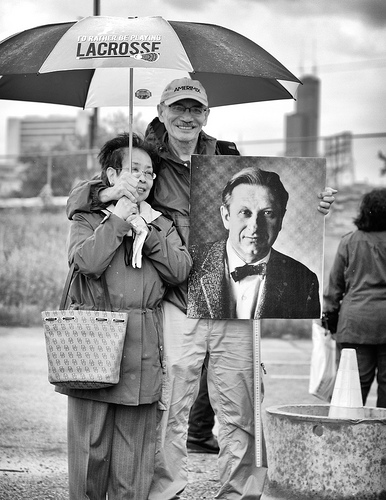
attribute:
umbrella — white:
[88, 20, 152, 31]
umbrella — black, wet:
[208, 29, 255, 105]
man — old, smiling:
[157, 82, 209, 156]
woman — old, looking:
[132, 148, 155, 204]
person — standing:
[335, 186, 384, 351]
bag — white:
[309, 328, 336, 400]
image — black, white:
[0, 12, 384, 499]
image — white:
[219, 107, 280, 138]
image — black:
[273, 268, 306, 315]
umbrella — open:
[0, 15, 271, 77]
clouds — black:
[368, 3, 384, 21]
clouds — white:
[342, 22, 358, 35]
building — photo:
[300, 43, 323, 152]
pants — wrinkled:
[163, 308, 188, 498]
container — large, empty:
[268, 403, 386, 498]